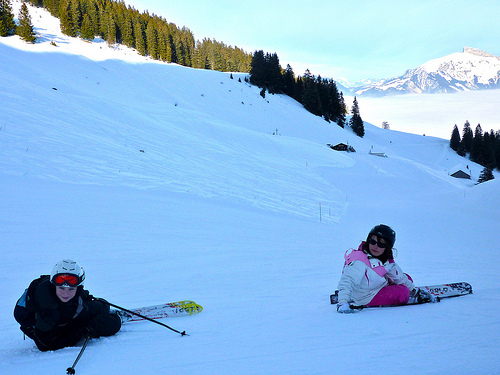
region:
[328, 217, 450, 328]
a young girl sitting on the ground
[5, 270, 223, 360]
a young boy sitting on the ground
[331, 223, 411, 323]
a young girl wearing a white and pink jacket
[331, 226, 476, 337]
a young girl wearing skis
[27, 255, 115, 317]
a young boy wearing red googles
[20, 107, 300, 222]
snow covering the ground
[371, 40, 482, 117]
snow covered mountain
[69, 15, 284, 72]
several trees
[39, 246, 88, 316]
a young boy wearing a white helmet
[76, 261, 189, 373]
two ski poles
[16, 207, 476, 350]
two people on top of snow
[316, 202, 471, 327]
female seated and turned around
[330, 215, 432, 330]
white jacket with pink trim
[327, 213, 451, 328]
knees bent in deep pink pants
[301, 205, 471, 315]
female resting on snowboard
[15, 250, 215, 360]
person seated and leaning over skis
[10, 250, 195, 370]
ski poles to side and front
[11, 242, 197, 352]
goggles raised onto helmet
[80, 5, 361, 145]
trees along mountain slope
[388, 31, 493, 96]
narrow ledge on top of broad mountain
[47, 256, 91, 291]
White helmet on a boy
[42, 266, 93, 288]
Orange goggles on a boy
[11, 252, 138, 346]
Boy wearing black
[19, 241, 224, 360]
boy sitting with skis on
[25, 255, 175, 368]
Boy holding ski poles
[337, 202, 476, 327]
Girl wearing pink and white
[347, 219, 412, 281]
Sunglasses on a girl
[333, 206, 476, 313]
Girl sitting in skis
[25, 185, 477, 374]
Kids sitting in snow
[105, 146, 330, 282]
White snow covered hill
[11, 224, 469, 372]
the kids are on the snow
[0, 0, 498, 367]
a lot of snow on the ground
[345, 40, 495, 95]
the mountain is covered in snow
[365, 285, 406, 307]
the girl wears pink pants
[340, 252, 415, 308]
the girl wears a white jacket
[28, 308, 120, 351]
the boy wears black pants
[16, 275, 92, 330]
the boys wears a black jacket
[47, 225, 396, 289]
the kids wear helmets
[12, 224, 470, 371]
the kids are skiing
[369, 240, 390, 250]
the girl wears glasses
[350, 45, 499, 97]
Snow covered mountains.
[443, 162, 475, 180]
A house with a snow covered rooftop.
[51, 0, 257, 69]
A forest growing on the side of a hill.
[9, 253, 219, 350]
A young boy skiing.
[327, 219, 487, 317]
A young girl skiing.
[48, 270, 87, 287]
Red and black ski goggles.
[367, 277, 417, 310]
Pink snow pants.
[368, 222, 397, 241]
A black ski helmet.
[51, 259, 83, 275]
A white ski helmet.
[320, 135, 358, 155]
A house with a snow covered rooftop.